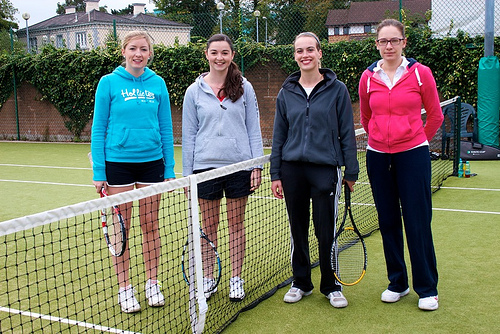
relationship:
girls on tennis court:
[86, 7, 443, 327] [2, 134, 499, 331]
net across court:
[11, 96, 463, 331] [0, 127, 500, 328]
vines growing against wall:
[2, 49, 484, 141] [5, 87, 290, 142]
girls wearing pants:
[266, 31, 358, 307] [274, 164, 441, 291]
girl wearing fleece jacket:
[360, 18, 442, 312] [359, 61, 441, 148]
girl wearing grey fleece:
[200, 33, 246, 100] [179, 27, 262, 194]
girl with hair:
[77, 24, 180, 301] [114, 20, 156, 45]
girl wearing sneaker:
[358, 18, 443, 312] [379, 285, 413, 300]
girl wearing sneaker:
[358, 18, 443, 312] [418, 290, 442, 310]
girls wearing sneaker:
[266, 31, 358, 307] [285, 282, 312, 300]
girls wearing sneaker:
[266, 31, 358, 307] [325, 292, 348, 306]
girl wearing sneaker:
[181, 33, 265, 302] [227, 276, 241, 298]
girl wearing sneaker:
[89, 30, 176, 314] [116, 283, 138, 310]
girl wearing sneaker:
[89, 30, 176, 314] [147, 278, 164, 303]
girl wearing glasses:
[358, 18, 443, 312] [375, 35, 405, 47]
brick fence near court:
[0, 56, 476, 143] [0, 127, 500, 328]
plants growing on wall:
[11, 34, 478, 79] [4, 88, 468, 143]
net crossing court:
[11, 96, 463, 331] [0, 127, 500, 328]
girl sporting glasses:
[358, 18, 443, 312] [375, 37, 405, 44]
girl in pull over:
[89, 30, 176, 314] [90, 62, 177, 183]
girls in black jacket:
[266, 31, 358, 307] [265, 66, 360, 188]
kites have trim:
[192, 167, 252, 199] [106, 180, 165, 182]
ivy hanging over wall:
[36, 33, 126, 97] [7, 84, 93, 144]